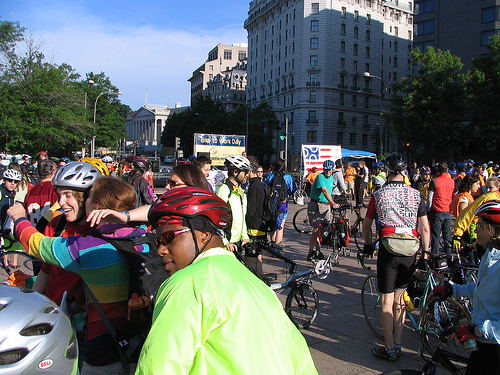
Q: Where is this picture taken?
A: City.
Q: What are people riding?
A: Bicycles.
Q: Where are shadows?
A: On the ground.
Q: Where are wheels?
A: On the bicycles.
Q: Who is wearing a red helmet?
A: Man in foreground.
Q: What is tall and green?
A: Trees.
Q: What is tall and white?
A: The buildings.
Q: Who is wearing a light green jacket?
A: Man in red helmet.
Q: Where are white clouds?
A: In the sky.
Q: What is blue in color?
A: The sky.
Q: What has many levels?
A: Building.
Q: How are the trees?
A: Tall.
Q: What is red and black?
A: Shirt.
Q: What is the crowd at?
A: Bike race.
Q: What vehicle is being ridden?
A: Bikes.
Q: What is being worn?
A: Helmets.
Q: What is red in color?
A: Helmets.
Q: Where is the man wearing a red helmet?
A: On the bike.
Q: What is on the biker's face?
A: Sunglasses.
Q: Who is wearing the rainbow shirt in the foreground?
A: A woman.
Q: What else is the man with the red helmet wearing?
A: Sunglasses.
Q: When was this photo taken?
A: At midday.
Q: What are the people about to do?
A: Race.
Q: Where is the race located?
A: In a city.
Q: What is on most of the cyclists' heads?
A: Helmets.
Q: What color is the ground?
A: Gray.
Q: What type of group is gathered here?
A: Group of cyclist.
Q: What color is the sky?
A: Blue.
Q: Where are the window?
A: On the building.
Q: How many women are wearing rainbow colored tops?
A: 1.